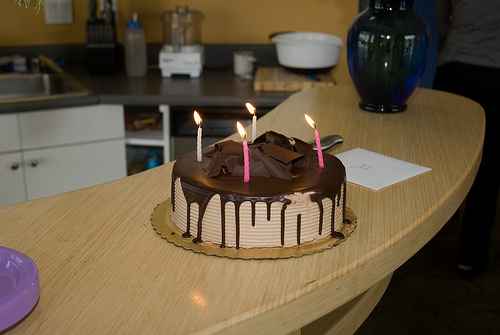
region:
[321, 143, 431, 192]
A white envelope on the counter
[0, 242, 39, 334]
A stack of purple plates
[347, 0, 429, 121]
A dark blue vase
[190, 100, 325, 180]
Four candles on a cake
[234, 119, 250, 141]
A flame on a candle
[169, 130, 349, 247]
A round chocolate cake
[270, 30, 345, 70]
A white bowl in the background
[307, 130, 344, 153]
A silver knife handle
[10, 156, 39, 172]
Metal cabinet door pulls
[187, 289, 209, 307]
The reflection of a flame on the counter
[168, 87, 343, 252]
Four lit candles on the cake.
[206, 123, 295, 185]
Chocolate curls on the cake.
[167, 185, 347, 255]
Frosting dripping down the cake.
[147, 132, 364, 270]
Cake sitting on a plate.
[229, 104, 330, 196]
Two pink candles are burning.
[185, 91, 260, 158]
Two white candles are aglow.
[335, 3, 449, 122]
Blue vase on the counter.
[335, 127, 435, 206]
White envelope on the counter.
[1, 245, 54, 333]
Purple plastic plates on the counter.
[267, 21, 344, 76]
White bowl on the counter.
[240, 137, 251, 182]
the pink candle on the cake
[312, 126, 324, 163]
the pink candle on the cake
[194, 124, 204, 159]
the white candle on the cake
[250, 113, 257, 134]
the white candle on the cake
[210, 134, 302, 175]
the chocolate shavings on a cake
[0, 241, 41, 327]
a pile of purple plastic plates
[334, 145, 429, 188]
a white envelope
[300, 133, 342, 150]
a silver metal handle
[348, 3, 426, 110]
a large blue glass vase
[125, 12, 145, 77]
a plastic drinking bottle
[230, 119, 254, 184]
PINK CANDLE ON BIRTHDAY CAKE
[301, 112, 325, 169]
PINK CANDLE ON BIRTHDAY CAKE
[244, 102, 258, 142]
WHITE CANDLE ON BIRTHDAY CAKE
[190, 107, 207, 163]
WHITE CANDLE ON BIRTHDAY CAKE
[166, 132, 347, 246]
CHOCOLATE DRIZZLE ON BIRTHDAY CAKE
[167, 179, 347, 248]
CREAM COLORED ICING ON BIRTHDAY CAKE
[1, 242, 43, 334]
PURPLE PLATES STACKED ON A KITCHEN BAR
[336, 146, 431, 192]
WHITE ENVELOPE BESIDE BIRTHDAY CAKE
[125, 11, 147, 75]
BABY BOTTLE WITH BLUE RING ON KITCHEN CABINET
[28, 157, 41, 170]
HARDWARE ON KITCHEN CABINET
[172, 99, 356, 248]
A birthday cake on the table.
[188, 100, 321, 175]
Candles on the cake.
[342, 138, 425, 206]
A white envelope on the table.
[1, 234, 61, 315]
Purple plates on the table.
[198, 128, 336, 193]
The cake is covered in chocolate.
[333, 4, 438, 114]
A blue vase on the counter.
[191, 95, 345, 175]
Four candles on the cake.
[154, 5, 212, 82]
A food processor on the counter.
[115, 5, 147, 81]
A water bottle next to the food processor.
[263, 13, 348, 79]
A white bowl on the counter.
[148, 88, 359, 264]
cake on a counter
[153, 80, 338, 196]
candles on the cake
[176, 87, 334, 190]
the candles are lit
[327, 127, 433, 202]
envelope on the counter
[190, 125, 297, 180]
a pile of chocolate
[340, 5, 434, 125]
vase on the counter